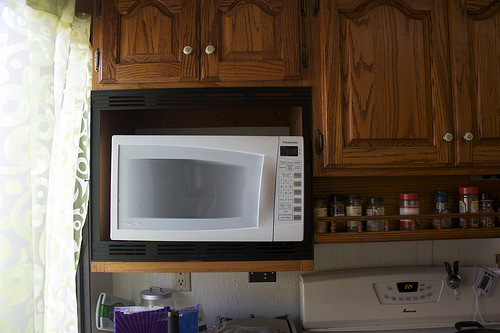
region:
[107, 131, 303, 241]
A microwave is in the kitchen.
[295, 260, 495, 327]
A digital oven is in the kitchen.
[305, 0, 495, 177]
A wooden cabinet is in the kitchen.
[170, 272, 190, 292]
A power outlet is near the microwave.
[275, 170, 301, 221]
The buttons used to operate the device.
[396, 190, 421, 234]
A jar full of spice below the cabinet.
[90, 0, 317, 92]
A smaller cabinet is above the microwave.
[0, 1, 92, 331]
A beautiful white curtain.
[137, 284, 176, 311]
A glass jar is below the microwave.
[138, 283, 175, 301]
A metallic lid is covering the jar.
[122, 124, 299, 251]
white microwave in kitchen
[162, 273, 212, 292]
tan electrical outlet under microwave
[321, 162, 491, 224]
small bottles of herbs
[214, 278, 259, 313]
white backsplash under microwave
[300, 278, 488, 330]
white range in kitchen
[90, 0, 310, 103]
brown doors on cabinets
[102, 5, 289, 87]
cabinets are above microwave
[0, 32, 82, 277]
white curtains on window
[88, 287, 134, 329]
green and white mop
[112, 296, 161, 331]
purple bag under microwave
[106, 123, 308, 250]
microwave in stand over counter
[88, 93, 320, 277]
stand built into cabinet space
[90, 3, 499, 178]
wooden cabinets with white knobs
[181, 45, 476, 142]
white knobs on wooden cabinets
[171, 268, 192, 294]
electrical plug underneath microwave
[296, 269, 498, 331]
top of white stove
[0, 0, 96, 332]
patterned curtains covering window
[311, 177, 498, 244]
spice assortment in wooden rack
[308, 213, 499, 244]
wooden spice rack underneath cabinet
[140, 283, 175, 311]
glass jar with metal lid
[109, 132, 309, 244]
a white microwave in a kitchen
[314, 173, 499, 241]
a wooden spice rack in a kitchen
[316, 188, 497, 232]
spice bottles on a spice rack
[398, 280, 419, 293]
digital display on a white oven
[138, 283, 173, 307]
a jar with a metal lid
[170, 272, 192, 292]
an electrical outlet on the wall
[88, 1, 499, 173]
wooden cabinets in a kitchen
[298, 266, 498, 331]
a white oven in a kitchen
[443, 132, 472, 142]
white round knobs on a wooden cabinet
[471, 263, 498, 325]
white wires on an oven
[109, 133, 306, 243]
white microwave in the frame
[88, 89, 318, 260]
black frame around microwave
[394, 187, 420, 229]
red and white spice bottle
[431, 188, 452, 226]
spice bottle with green cap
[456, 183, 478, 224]
spice bottle with red cap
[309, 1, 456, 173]
brown wood cabin above stove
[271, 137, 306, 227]
alot of controls for the microwav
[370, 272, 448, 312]
controls for the stove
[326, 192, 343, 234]
spice bottle with black cap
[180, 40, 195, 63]
white door knob on cabinet door